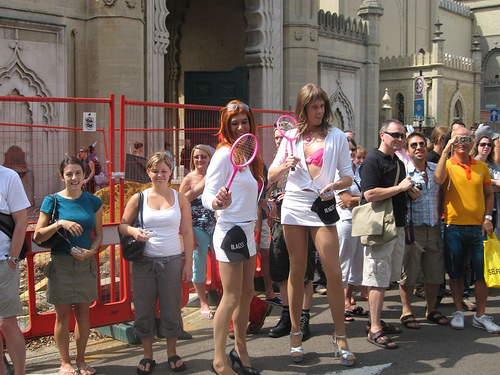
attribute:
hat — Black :
[445, 114, 493, 154]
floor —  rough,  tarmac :
[2, 284, 498, 371]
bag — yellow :
[483, 233, 498, 286]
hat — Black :
[213, 214, 284, 264]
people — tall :
[215, 90, 365, 361]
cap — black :
[226, 232, 248, 267]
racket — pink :
[217, 131, 259, 210]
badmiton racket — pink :
[212, 139, 266, 195]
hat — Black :
[220, 225, 252, 265]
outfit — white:
[191, 139, 276, 274]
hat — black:
[214, 214, 255, 259]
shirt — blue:
[276, 122, 409, 224]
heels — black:
[207, 342, 258, 374]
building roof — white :
[322, 7, 365, 44]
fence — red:
[1, 92, 310, 343]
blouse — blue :
[39, 191, 101, 254]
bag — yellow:
[480, 230, 498, 289]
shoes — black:
[193, 335, 268, 374]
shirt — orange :
[446, 156, 488, 230]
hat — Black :
[214, 220, 260, 267]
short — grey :
[126, 253, 190, 340]